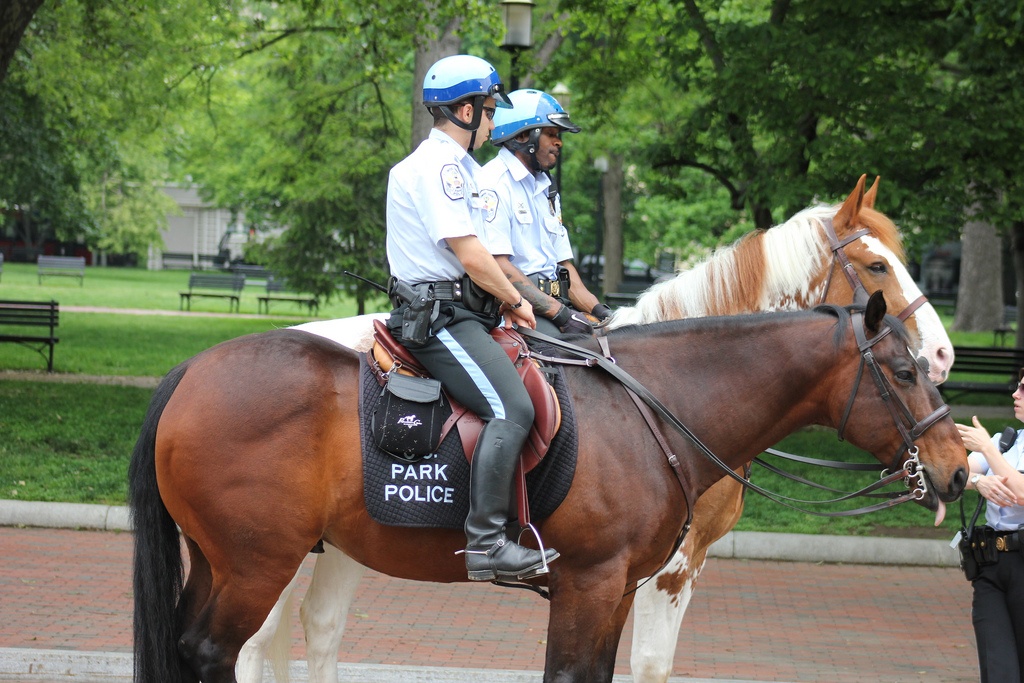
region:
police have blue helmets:
[377, 64, 608, 181]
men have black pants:
[447, 284, 523, 556]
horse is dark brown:
[201, 336, 979, 678]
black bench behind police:
[0, 260, 99, 415]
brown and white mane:
[649, 173, 877, 351]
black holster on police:
[377, 263, 467, 341]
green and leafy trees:
[81, 12, 1011, 234]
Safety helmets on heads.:
[429, 55, 570, 150]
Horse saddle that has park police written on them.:
[363, 319, 566, 534]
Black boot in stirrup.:
[461, 417, 559, 579]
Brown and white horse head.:
[609, 159, 970, 376]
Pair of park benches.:
[174, 266, 336, 317]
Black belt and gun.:
[378, 269, 484, 349]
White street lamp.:
[488, 0, 537, 81]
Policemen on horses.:
[109, 60, 977, 661]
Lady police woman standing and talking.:
[935, 377, 1022, 679]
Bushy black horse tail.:
[104, 377, 178, 679]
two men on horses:
[389, 38, 590, 555]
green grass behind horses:
[0, 366, 90, 503]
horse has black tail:
[55, 357, 253, 678]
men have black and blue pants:
[468, 328, 529, 526]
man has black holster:
[389, 237, 470, 377]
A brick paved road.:
[1, 510, 1022, 679]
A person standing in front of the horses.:
[946, 368, 1022, 681]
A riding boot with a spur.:
[440, 412, 565, 589]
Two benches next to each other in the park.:
[159, 263, 333, 322]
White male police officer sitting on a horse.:
[361, 48, 571, 589]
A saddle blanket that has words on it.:
[352, 311, 581, 543]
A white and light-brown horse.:
[226, 172, 960, 681]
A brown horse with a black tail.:
[110, 298, 978, 681]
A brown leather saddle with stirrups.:
[359, 311, 568, 591]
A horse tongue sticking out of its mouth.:
[918, 479, 960, 540]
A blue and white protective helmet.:
[416, 44, 515, 112]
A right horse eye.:
[855, 253, 890, 279]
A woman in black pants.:
[943, 373, 1021, 680]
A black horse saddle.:
[352, 344, 584, 529]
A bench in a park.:
[0, 292, 61, 368]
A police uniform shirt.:
[382, 128, 513, 288]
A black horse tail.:
[123, 351, 191, 675]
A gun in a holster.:
[378, 276, 456, 346]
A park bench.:
[173, 267, 253, 315]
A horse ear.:
[831, 164, 871, 248]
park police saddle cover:
[355, 328, 483, 547]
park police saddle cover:
[348, 300, 505, 542]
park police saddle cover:
[340, 307, 489, 557]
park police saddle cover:
[346, 293, 489, 551]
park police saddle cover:
[336, 290, 510, 560]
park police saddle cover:
[351, 316, 583, 545]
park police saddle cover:
[346, 315, 593, 550]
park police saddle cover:
[358, 310, 589, 549]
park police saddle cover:
[339, 306, 583, 562]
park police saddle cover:
[336, 298, 592, 554]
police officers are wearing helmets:
[417, 48, 576, 180]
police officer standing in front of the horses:
[949, 357, 1021, 677]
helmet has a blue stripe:
[423, 42, 513, 115]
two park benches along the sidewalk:
[169, 261, 324, 317]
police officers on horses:
[382, 44, 631, 606]